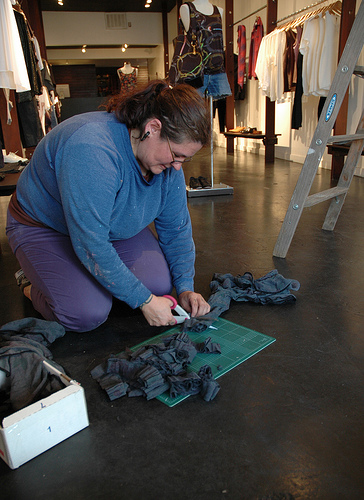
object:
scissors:
[158, 290, 220, 334]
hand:
[138, 293, 180, 330]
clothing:
[2, 317, 63, 409]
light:
[78, 40, 96, 63]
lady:
[3, 74, 218, 334]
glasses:
[158, 127, 192, 166]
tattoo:
[136, 291, 158, 305]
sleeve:
[44, 150, 210, 309]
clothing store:
[0, 0, 364, 500]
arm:
[50, 144, 154, 306]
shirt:
[10, 107, 197, 307]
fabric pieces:
[210, 271, 300, 310]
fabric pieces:
[0, 318, 62, 389]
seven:
[39, 401, 45, 407]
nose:
[168, 155, 185, 171]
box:
[2, 342, 97, 473]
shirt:
[317, 4, 344, 93]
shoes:
[0, 146, 24, 183]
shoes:
[229, 122, 262, 135]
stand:
[0, 94, 33, 198]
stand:
[221, 90, 282, 164]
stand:
[182, 98, 238, 200]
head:
[121, 66, 211, 180]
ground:
[241, 84, 283, 114]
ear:
[145, 119, 163, 140]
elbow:
[66, 226, 110, 260]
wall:
[271, 105, 290, 128]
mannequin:
[180, 0, 235, 199]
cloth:
[140, 273, 258, 341]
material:
[91, 259, 302, 412]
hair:
[107, 62, 214, 151]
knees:
[47, 277, 115, 334]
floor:
[0, 145, 362, 497]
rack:
[266, 1, 364, 261]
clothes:
[255, 11, 341, 103]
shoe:
[188, 175, 201, 190]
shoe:
[197, 173, 210, 189]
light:
[120, 40, 127, 52]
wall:
[41, 9, 164, 87]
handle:
[161, 292, 178, 311]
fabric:
[88, 264, 301, 407]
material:
[0, 315, 66, 418]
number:
[43, 423, 52, 432]